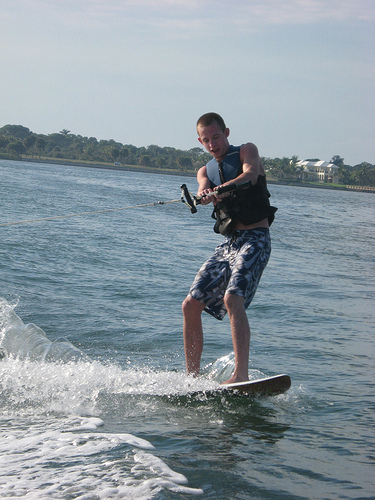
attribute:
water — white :
[0, 296, 267, 493]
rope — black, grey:
[91, 178, 201, 230]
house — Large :
[288, 157, 342, 184]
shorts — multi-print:
[186, 231, 304, 339]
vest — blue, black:
[204, 145, 276, 232]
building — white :
[283, 153, 349, 184]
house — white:
[292, 153, 341, 188]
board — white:
[157, 346, 294, 429]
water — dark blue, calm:
[0, 157, 372, 498]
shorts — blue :
[187, 223, 277, 315]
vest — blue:
[201, 144, 280, 238]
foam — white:
[0, 287, 334, 499]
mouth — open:
[208, 147, 221, 155]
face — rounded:
[196, 120, 225, 158]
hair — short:
[196, 112, 226, 137]